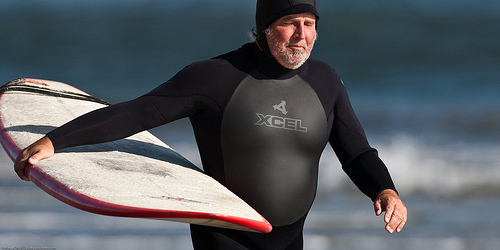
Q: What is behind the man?
A: Ocean.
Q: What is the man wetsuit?
A: Black.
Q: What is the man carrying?
A: Surfboard.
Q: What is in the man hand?
A: Red and white surfboard.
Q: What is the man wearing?
A: Black bodysuit.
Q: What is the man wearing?
A: Black surf suit.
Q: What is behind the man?
A: Ocean waves.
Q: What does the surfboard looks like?
A: Red and white.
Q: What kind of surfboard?
A: A red and white one.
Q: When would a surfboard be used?
A: While surfing.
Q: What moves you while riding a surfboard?
A: The waves.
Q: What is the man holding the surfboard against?
A: His side.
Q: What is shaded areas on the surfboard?
A: A shadow.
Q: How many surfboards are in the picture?
A: One.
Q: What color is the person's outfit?
A: Black.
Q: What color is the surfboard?
A: White.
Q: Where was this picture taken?
A: At the beach.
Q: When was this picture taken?
A: During the day.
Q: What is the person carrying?
A: A surfboard.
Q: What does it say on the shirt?
A: XCEL.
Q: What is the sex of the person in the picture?
A: Male.